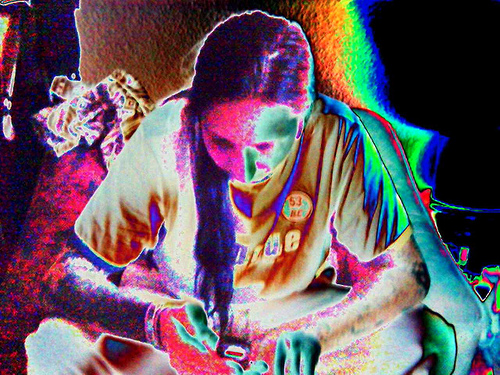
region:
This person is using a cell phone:
[230, 324, 253, 358]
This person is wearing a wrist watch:
[146, 303, 173, 358]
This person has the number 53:
[291, 185, 310, 244]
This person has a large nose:
[236, 144, 256, 188]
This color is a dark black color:
[456, 13, 473, 75]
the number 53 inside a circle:
[282, 188, 312, 221]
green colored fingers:
[271, 330, 326, 373]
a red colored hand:
[159, 305, 234, 374]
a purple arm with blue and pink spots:
[36, 244, 162, 350]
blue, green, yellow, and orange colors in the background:
[295, 2, 462, 214]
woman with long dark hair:
[41, 8, 429, 372]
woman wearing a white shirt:
[43, 16, 420, 371]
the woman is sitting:
[23, 8, 424, 374]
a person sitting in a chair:
[27, 23, 472, 353]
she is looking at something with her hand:
[187, 114, 307, 369]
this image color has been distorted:
[16, 14, 481, 374]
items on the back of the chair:
[34, 73, 146, 138]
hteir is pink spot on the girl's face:
[192, 92, 308, 199]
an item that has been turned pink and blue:
[22, 150, 88, 311]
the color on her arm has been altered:
[39, 258, 161, 337]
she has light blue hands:
[267, 324, 329, 373]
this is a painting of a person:
[5, 16, 467, 372]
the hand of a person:
[51, 95, 256, 372]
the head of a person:
[164, 0, 324, 192]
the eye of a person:
[214, 125, 234, 160]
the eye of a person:
[252, 137, 272, 161]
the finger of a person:
[293, 331, 309, 372]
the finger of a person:
[274, 336, 286, 372]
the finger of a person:
[281, 338, 296, 373]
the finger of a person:
[177, 313, 219, 345]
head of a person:
[153, 18, 334, 192]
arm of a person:
[43, 133, 170, 371]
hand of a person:
[156, 301, 213, 373]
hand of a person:
[252, 322, 327, 373]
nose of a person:
[237, 161, 259, 188]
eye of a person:
[206, 129, 291, 161]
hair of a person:
[177, 123, 265, 351]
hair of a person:
[202, 15, 312, 102]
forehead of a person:
[195, 108, 316, 143]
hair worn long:
[194, 8, 318, 324]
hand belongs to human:
[158, 299, 228, 374]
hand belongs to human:
[243, 322, 323, 374]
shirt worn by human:
[74, 85, 411, 305]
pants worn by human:
[22, 282, 461, 374]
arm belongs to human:
[30, 100, 177, 350]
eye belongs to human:
[212, 137, 233, 154]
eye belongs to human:
[257, 142, 275, 150]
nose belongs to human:
[233, 146, 251, 181]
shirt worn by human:
[73, 92, 408, 309]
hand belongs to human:
[268, 325, 319, 374]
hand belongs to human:
[155, 302, 219, 369]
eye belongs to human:
[254, 138, 273, 153]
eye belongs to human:
[212, 133, 234, 154]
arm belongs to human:
[312, 101, 437, 359]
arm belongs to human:
[29, 112, 175, 342]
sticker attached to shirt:
[279, 190, 310, 224]